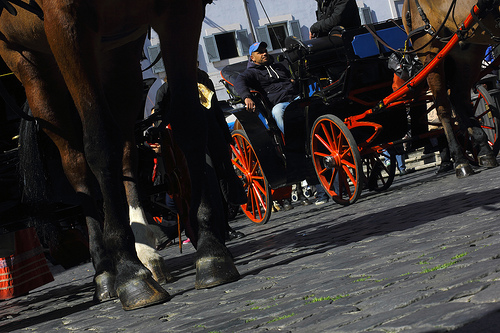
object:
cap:
[248, 41, 268, 54]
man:
[233, 41, 301, 135]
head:
[250, 42, 270, 62]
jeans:
[271, 95, 304, 134]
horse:
[400, 0, 498, 179]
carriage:
[221, 0, 500, 227]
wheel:
[309, 114, 363, 205]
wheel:
[459, 82, 499, 167]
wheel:
[359, 149, 396, 191]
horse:
[0, 0, 242, 312]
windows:
[267, 23, 289, 50]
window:
[212, 31, 239, 60]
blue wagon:
[217, 0, 500, 225]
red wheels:
[229, 130, 271, 225]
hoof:
[455, 163, 475, 178]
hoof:
[478, 153, 500, 168]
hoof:
[194, 253, 241, 290]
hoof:
[117, 276, 168, 314]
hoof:
[88, 271, 117, 302]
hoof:
[140, 256, 168, 285]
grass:
[304, 292, 344, 306]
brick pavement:
[0, 167, 497, 331]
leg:
[120, 156, 161, 256]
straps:
[364, 0, 456, 55]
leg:
[44, 21, 143, 258]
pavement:
[7, 143, 497, 331]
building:
[127, 2, 423, 135]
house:
[140, 4, 377, 113]